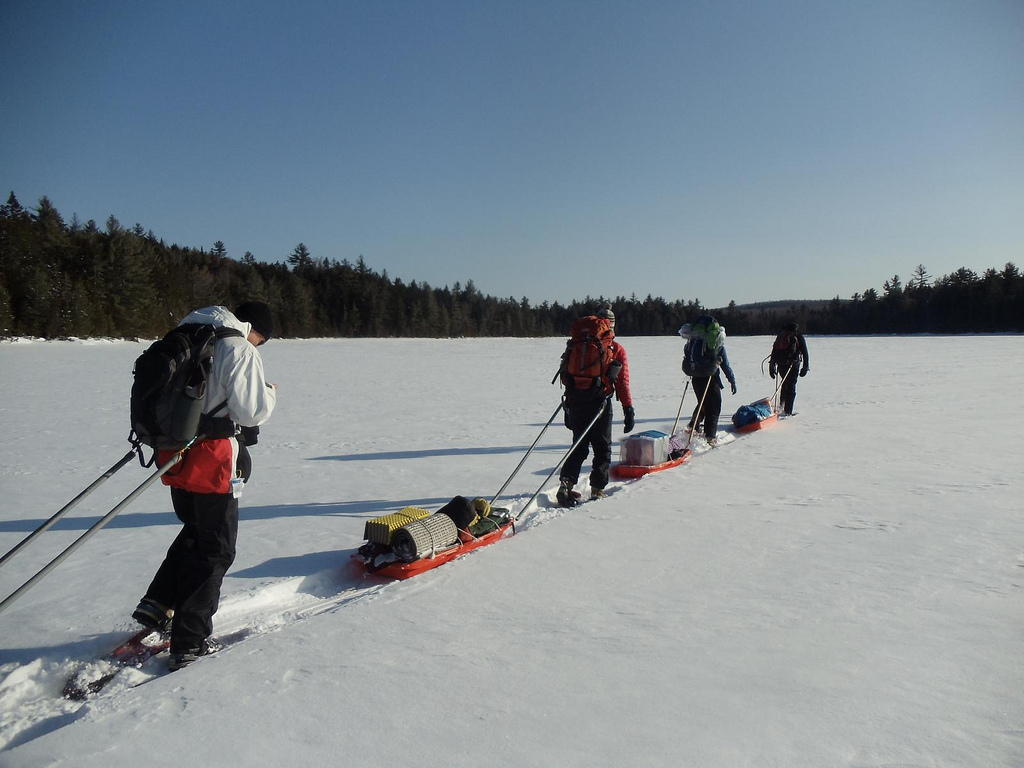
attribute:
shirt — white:
[101, 311, 320, 471]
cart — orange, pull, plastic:
[353, 480, 821, 573]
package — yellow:
[347, 463, 510, 559]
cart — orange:
[347, 463, 510, 559]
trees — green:
[81, 214, 1008, 345]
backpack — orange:
[584, 317, 698, 419]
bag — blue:
[707, 369, 867, 471]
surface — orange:
[707, 369, 867, 471]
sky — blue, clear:
[400, 47, 879, 266]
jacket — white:
[119, 320, 385, 548]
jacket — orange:
[552, 296, 709, 456]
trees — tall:
[90, 232, 739, 331]